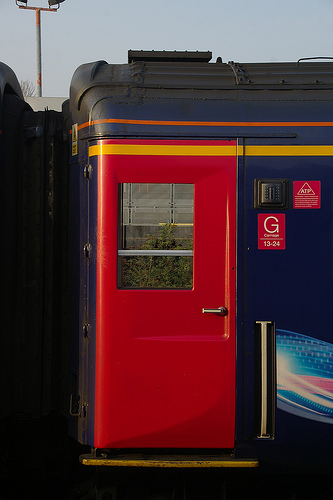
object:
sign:
[257, 212, 285, 250]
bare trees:
[20, 77, 37, 98]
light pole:
[13, 0, 65, 96]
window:
[117, 180, 197, 290]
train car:
[67, 48, 333, 500]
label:
[292, 181, 320, 210]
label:
[258, 213, 286, 251]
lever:
[202, 306, 228, 317]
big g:
[264, 215, 280, 233]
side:
[73, 97, 333, 454]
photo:
[0, 0, 333, 500]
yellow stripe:
[89, 140, 333, 158]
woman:
[32, 6, 44, 98]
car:
[61, 49, 333, 500]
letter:
[264, 216, 279, 234]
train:
[0, 45, 333, 500]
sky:
[0, 0, 333, 103]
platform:
[81, 451, 261, 471]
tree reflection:
[118, 183, 195, 290]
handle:
[202, 306, 228, 317]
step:
[79, 452, 259, 470]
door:
[92, 135, 237, 453]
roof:
[72, 48, 333, 139]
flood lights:
[11, 0, 66, 10]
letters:
[264, 233, 281, 247]